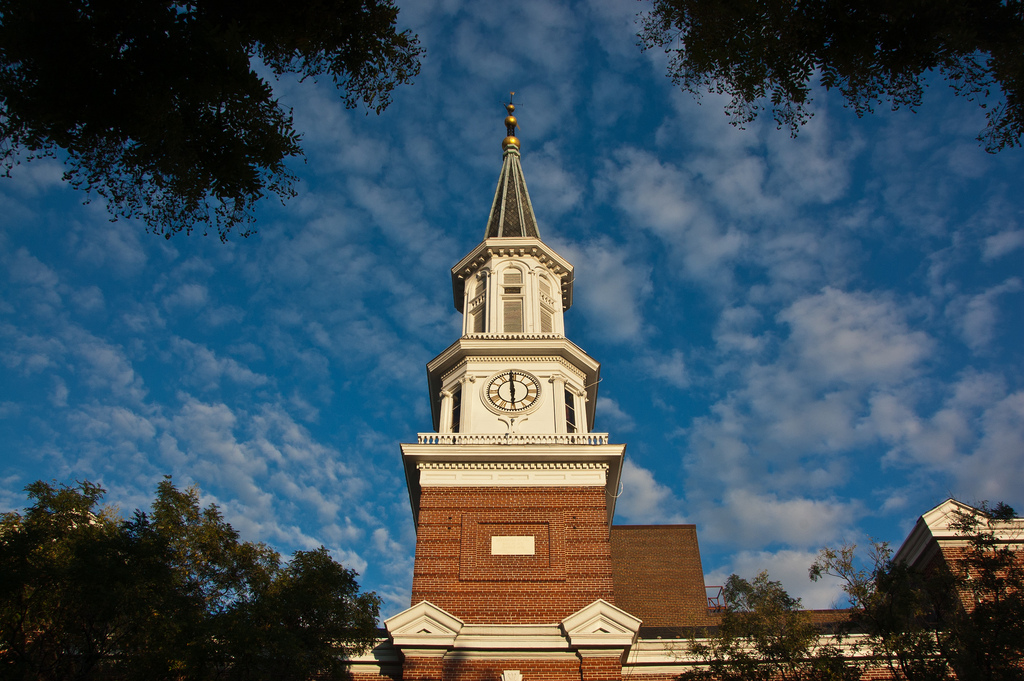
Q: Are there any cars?
A: No, there are no cars.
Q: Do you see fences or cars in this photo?
A: No, there are no cars or fences.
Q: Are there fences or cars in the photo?
A: No, there are no cars or fences.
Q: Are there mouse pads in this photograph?
A: No, there are no mouse pads.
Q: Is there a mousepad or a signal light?
A: No, there are no mouse pads or traffic lights.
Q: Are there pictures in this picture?
A: No, there are no pictures.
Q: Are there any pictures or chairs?
A: No, there are no pictures or chairs.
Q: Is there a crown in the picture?
A: Yes, there is a crown.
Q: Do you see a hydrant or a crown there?
A: Yes, there is a crown.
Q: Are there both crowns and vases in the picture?
A: No, there is a crown but no vases.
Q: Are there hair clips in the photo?
A: No, there are no hair clips.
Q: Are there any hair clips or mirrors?
A: No, there are no hair clips or mirrors.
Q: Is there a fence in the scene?
A: No, there are no fences.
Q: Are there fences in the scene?
A: No, there are no fences.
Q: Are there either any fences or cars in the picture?
A: No, there are no fences or cars.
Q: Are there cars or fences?
A: No, there are no fences or cars.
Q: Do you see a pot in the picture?
A: No, there are no pots.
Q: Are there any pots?
A: No, there are no pots.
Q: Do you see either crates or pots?
A: No, there are no pots or crates.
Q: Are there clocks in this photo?
A: Yes, there is a clock.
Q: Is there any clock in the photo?
A: Yes, there is a clock.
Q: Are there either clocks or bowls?
A: Yes, there is a clock.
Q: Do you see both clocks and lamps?
A: No, there is a clock but no lamps.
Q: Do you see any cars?
A: No, there are no cars.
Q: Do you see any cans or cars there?
A: No, there are no cars or cans.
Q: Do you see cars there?
A: No, there are no cars.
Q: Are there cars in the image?
A: No, there are no cars.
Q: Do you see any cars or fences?
A: No, there are no cars or fences.